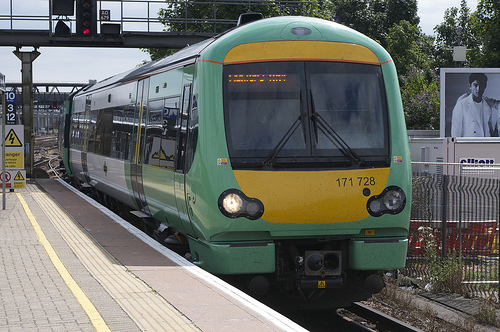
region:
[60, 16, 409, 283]
the train is green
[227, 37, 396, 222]
the train has a yellow face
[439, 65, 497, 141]
the ad has a man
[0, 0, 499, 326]
scene takes place outdoors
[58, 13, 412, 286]
the train is on the tracks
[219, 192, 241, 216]
the light is on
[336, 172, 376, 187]
the train has numbers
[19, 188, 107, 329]
the platform has yellow stripe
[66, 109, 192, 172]
the train has many windows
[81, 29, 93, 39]
the light is red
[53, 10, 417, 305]
aqua and yellow train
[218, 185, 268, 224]
one headlight lit on train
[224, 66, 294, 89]
orange destination digitel display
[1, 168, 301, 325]
concrete stone platform made of bricks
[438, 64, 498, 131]
black and white billboard ad with man in white shirt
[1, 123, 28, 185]
yellow caution and warning signs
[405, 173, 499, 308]
metal fence near tracks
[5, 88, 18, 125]
white numbers on blue and black sign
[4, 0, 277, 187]
overhead metal crosswalk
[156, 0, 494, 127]
green trees in background behind train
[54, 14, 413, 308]
black, green and yellow train on the tracks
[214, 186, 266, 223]
headlight that's turned on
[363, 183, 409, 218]
headlights that aren't turned on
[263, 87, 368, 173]
black wipers on the train's windshield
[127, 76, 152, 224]
door on the green and yellow train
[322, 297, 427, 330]
railroad tracks under the train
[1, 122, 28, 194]
white and yellow sign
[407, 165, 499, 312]
fence near the train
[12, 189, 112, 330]
yellow line on the sidewalk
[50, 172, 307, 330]
white curb on the sidewalk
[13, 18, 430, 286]
A green and yellow train on the rails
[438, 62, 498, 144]
A grey and white advertisement by the train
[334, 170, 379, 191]
The number of the train is 171 728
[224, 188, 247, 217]
One headlight of the train is on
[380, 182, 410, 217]
The right head light on the train is turned off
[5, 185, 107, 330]
A thin yellow line painted on the ground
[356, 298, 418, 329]
Metal rails beneath the train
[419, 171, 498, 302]
A small black fence by the train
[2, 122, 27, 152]
A white sign warning of electrical hazards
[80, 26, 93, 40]
A small red light above the train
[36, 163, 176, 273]
A long black shadow near the train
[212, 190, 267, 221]
One of the train's headlights is powered on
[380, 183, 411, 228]
The train's right headlight is turned off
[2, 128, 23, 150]
A yellow and black triangle on the white sign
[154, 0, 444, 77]
Healthy green trees behind the train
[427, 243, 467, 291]
Small green vegetation near the fence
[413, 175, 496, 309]
A short black fence near the train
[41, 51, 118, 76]
The sky looks clear and blue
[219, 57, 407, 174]
A large window on the front of the train